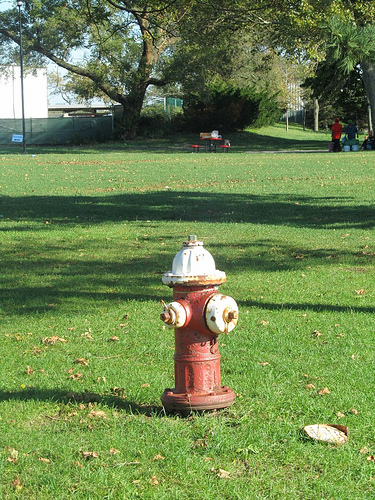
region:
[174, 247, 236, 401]
a red and white fire hydrant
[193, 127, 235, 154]
red table sitting on the grass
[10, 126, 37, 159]
a white sign with black letters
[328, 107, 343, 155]
a man wearing a red shirt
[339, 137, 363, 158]
white buckets sitting on the ground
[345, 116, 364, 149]
man wearing a green hat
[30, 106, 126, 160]
a fence around a building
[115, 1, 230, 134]
a tree growing beside a fence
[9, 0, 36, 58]
a light pole beside the fence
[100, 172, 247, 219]
green grass with leaves on it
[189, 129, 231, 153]
Picnic table with red seats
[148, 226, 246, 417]
Fire hydrant in the grass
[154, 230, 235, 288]
Top of fire hydrant is white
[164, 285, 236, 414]
Body of fire hydrant is red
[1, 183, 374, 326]
Shadows of trees in grass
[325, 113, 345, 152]
Person wearing a red shirt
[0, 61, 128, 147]
Building behind the fence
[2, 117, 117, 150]
Green fence with a white sign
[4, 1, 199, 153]
Large, old tree in back of park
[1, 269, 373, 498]
Leaves in the grass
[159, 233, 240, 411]
a red fire hydrant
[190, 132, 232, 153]
a red and black picnic table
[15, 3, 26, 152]
a tall black pole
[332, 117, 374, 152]
a group of people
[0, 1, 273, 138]
a big oak tree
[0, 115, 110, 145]
a green chain-linked fence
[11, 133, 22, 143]
a sign with directions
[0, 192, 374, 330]
a large shadow of a tree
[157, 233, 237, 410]
an old fire hydrant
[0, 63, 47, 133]
a big white building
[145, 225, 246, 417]
fire hydrant on the ground.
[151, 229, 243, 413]
the fire hydrant is red and white.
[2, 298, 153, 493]
leaves on the ground.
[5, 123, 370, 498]
the grass is green.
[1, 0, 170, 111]
the sky is blue.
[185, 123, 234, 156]
bench in the grass.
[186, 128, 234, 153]
the bench is red.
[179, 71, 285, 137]
the bush is green.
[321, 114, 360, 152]
people standing in the grass.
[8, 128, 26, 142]
the sign is white.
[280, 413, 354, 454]
a piece of paper lying on the grass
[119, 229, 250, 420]
a red and yellow fire hydrant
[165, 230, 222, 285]
yellow tip of fire hydrant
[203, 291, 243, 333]
a plug that comes off fire hydrant that is yellow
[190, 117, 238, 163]
a picnic table with red seats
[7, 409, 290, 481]
leaves on top of green grass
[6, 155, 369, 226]
green grassy field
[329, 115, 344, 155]
a person in a red jacket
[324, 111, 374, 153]
many people waiting under a tree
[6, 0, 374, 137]
many tall green shady trees